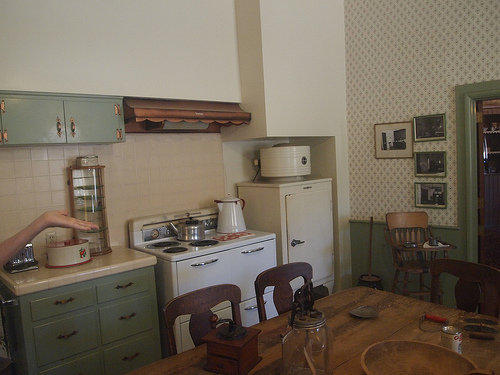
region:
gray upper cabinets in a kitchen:
[2, 87, 125, 152]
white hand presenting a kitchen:
[6, 208, 108, 258]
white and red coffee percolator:
[211, 192, 248, 237]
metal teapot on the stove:
[166, 215, 212, 245]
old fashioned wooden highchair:
[378, 205, 449, 286]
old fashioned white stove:
[130, 205, 290, 319]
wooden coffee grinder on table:
[198, 310, 267, 372]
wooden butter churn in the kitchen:
[351, 214, 381, 294]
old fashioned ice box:
[257, 177, 352, 295]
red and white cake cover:
[41, 231, 99, 271]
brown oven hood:
[122, 95, 251, 135]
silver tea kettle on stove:
[166, 218, 207, 241]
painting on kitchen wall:
[368, 115, 415, 161]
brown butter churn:
[356, 214, 383, 289]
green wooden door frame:
[453, 90, 480, 265]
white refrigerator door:
[278, 179, 338, 258]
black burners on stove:
[151, 238, 188, 256]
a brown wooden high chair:
[385, 208, 451, 295]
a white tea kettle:
[213, 192, 252, 235]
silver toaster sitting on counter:
[8, 240, 37, 274]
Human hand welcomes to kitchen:
[3, 173, 131, 265]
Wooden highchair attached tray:
[379, 197, 455, 294]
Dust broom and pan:
[358, 211, 385, 291]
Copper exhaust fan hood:
[112, 85, 255, 145]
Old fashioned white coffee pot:
[212, 184, 252, 241]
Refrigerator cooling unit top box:
[254, 141, 346, 290]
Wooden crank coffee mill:
[195, 310, 265, 372]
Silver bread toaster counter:
[2, 237, 42, 277]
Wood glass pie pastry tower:
[65, 154, 120, 261]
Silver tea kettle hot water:
[125, 208, 219, 288]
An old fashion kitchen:
[12, 27, 484, 365]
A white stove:
[114, 190, 311, 332]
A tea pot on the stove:
[156, 185, 252, 271]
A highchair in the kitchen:
[370, 196, 460, 293]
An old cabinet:
[230, 157, 350, 307]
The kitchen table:
[119, 256, 466, 368]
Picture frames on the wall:
[370, 99, 458, 247]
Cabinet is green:
[2, 72, 131, 160]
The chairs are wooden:
[132, 243, 349, 363]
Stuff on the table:
[224, 302, 486, 372]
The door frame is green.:
[450, 77, 499, 267]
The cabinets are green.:
[0, 85, 130, 154]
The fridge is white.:
[231, 170, 347, 302]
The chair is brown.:
[381, 204, 454, 294]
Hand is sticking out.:
[0, 202, 101, 279]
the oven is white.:
[125, 199, 288, 358]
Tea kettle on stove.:
[162, 206, 207, 243]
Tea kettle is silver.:
[165, 209, 207, 243]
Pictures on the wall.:
[367, 109, 452, 211]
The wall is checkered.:
[342, 0, 496, 233]